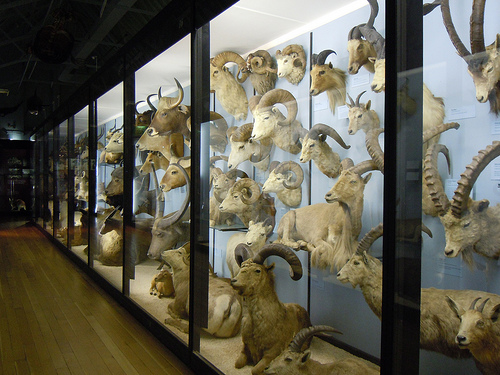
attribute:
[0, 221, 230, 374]
mat — brown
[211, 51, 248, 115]
head — mounted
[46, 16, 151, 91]
ceiling — white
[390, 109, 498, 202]
horn — sharp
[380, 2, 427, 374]
pillar — black 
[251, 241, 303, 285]
horn — curved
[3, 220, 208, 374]
flooring — hard wood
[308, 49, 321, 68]
curved horn — black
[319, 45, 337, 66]
curved horn — black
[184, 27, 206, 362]
frame — black 